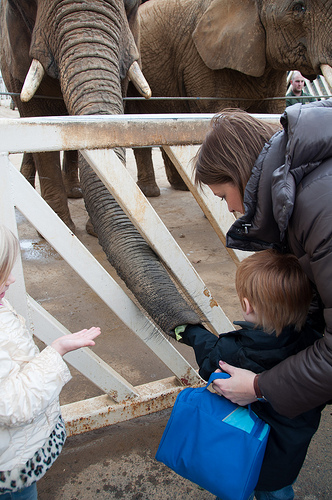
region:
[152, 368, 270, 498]
Blue bag with a handle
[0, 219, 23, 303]
Blonde hair on girl's head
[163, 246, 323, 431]
Little boy feeding an elephant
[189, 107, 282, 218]
Brown hair on woman's head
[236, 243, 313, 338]
Red hair on boy's head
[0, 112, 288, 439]
A white and dirty fence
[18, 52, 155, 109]
Two white elephant tusks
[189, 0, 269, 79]
Big ear of an elephant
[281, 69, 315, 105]
Man wearing a green shirt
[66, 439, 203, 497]
Black spots on the pavement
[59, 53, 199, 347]
a trunk of an elephant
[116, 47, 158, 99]
a task of an elephant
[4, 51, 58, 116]
a task of an elephant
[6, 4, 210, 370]
this is an elephant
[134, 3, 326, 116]
this is an elephant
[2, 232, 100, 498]
this is a person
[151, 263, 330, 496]
this is a person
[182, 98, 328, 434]
this is a person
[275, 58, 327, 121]
this is a person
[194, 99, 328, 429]
This is a woman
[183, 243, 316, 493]
This is a child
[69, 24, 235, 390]
Trunk of an elephant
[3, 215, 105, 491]
This is a child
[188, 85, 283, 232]
This is a woman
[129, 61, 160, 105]
A small elephant tusk.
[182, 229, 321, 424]
A young boy feeding an elephant.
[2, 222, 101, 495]
A young girl staring at her hand.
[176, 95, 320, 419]
A mother helping her son.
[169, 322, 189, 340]
Leaves in the elephant's tusk.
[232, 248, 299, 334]
Red hair on a young boy.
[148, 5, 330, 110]
A second large elephant in the background.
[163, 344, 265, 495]
A hand holding a lunch box.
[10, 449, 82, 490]
Leopard print on the coat.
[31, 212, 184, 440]
Metal poles protecting the people.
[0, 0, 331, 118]
Tow large brown elephants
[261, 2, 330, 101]
A man wearing a green shirt standing next to elephant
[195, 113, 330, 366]
A woman with her arms around a child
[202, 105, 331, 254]
A dark haired woman wearing a coat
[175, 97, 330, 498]
A dark haired woman holding a blue bag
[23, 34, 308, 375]
A child feeding an elephant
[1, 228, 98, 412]
A blonde haired girl wearing a white coat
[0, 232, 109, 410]
A blonde haired girl holding out her hand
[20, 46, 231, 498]
An elephant trunk with white tusks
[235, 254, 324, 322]
A small boy with red hair